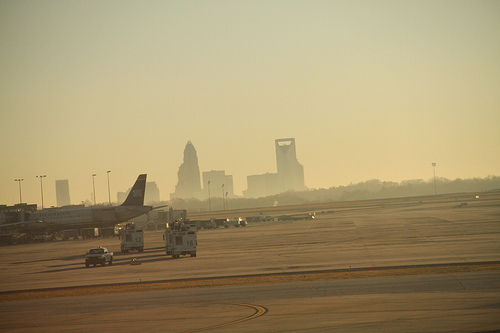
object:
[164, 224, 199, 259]
truck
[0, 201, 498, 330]
airport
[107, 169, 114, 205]
pole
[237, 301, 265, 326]
line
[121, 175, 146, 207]
tail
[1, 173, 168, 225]
plane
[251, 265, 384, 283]
grass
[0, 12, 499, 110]
sky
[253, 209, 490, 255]
runway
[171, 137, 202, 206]
building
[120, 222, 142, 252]
vehicle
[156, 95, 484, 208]
city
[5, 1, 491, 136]
background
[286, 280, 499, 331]
ground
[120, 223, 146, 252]
car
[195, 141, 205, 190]
edge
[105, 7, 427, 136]
day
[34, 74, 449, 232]
distance